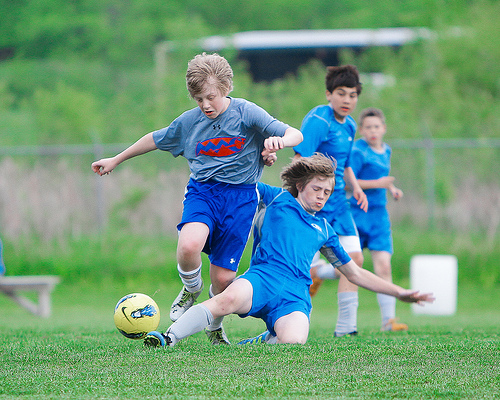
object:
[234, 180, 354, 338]
uniform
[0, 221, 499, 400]
grass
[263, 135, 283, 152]
hand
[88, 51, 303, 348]
boy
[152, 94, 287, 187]
shirt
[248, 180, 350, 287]
shirt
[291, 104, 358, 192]
shirt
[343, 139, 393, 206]
shirt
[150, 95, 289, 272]
uniform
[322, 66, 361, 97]
dark hair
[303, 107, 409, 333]
kid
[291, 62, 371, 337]
kid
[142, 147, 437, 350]
boy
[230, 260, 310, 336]
shorts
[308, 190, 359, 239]
shorts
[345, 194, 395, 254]
shorts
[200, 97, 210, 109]
nose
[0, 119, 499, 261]
fence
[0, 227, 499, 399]
field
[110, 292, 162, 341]
soccer ball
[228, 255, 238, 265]
logo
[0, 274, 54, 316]
bench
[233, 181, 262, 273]
stripe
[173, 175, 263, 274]
pants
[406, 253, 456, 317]
object